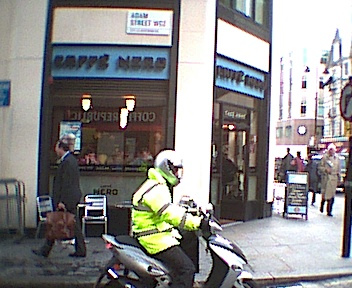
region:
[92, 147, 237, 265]
man in a bright yellow jacket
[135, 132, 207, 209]
shiny silver helmet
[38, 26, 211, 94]
blue and black sign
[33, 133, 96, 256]
man carrying a brown bag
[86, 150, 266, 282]
man riding a silver motorcycle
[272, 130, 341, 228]
people walking on a sidewalk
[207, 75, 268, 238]
doorframe of glass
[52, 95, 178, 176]
coffee shop with large windows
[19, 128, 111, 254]
man wearing a black suit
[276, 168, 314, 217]
coffee shop menu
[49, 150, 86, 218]
THE MAN IS WEARING A BLACK JACKET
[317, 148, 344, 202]
THE MAN IS WEARING A TRENCH COAT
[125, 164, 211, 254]
THE MAN IS WEARING A YELLOW JACKET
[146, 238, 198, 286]
THE MAN IS WEARING BLACK PANTS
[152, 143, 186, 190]
THE MAN IS WEARING A SILVER HELMET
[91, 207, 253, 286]
THE MAN IS ON A SCOOTER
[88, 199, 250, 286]
THE SCOOTER IS SILVER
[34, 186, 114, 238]
THE CHAIRS ARE WHITE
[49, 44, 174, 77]
THE SIGN IS BLUE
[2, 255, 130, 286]
THE SIDEWALK IS WET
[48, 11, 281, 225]
A storefront.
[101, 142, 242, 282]
A person on a motor scooter.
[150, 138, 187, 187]
The person is wearing a helmet.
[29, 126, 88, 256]
The man is walking down the sidewalk.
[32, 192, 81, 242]
The man is carrying a brown bag.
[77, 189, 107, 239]
An empty chair.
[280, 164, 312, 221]
A sign for the cafe.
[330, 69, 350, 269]
A street sign.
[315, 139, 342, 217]
The man is wearing a brown coat.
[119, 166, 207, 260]
The person is wearing a fluorescent yellow jacket.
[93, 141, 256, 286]
man on a moped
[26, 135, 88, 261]
male pedestrian with a briefcase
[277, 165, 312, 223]
restaurant sign on sidewalk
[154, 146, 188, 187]
helmet on a man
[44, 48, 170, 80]
name of a restaurant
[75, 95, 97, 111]
light on a ceiling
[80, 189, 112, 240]
chair outside a restaurant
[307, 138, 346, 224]
person walking on a sidewalk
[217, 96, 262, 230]
door to a restaurant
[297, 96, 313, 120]
window of a building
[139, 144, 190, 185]
helmet of the person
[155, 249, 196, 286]
leg of the person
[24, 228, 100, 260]
two legs of the person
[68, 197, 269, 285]
a small nice bike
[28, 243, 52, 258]
shoe of the person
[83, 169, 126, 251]
an nice iron chair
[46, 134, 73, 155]
face of the person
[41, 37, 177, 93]
name of the resturant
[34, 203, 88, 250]
a small bag holding by person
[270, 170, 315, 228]
a small advertisement board